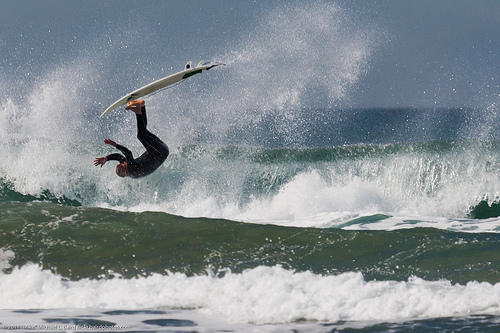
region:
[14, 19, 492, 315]
He is in the ocean.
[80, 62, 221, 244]
He is surfing.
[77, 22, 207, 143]
the board is white and black.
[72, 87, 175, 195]
He is wearing a wet suit.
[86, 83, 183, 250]
He is wet.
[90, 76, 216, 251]
He is upside down.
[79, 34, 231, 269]
he is falling.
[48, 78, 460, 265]
The wave is large.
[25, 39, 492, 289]
The wave is splashing.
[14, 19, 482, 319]
The water is dirty.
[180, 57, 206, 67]
The fins on the bottom of the surfboard.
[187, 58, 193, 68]
The fin on the bottom of the surfboard with a black circle.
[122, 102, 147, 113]
The feet of the surfer.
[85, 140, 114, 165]
The hands of the surfer.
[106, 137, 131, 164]
The arms of the surfer.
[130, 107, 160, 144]
The legs of the surfer.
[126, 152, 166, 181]
The chest and back area of the surfer.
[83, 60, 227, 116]
The surfboard the surfer is riding.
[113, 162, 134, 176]
The head of the surfer.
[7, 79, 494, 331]
The waves of the ocean.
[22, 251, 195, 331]
froth from the breaking wave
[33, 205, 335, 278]
wave in the ocean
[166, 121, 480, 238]
wave breaking in the ocean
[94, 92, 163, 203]
man falling in the air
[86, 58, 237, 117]
surfboard in the air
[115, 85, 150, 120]
man's feet leaving surfboard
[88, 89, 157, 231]
upside down man in ocean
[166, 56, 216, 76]
fins on the bottom of surfboard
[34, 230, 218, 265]
water in the ocean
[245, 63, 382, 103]
water droplets in the air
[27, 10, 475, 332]
man surfing on waves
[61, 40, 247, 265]
man on a surfboard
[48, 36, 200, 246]
man upside down in air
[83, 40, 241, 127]
white short surfboard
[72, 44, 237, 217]
man wearing a wet suit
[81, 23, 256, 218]
man falling down in air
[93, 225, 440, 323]
crashing waves in ocean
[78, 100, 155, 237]
man bent over upside down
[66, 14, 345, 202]
white water spraying in the air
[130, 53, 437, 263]
ocean and horizon line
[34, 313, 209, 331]
foam on the water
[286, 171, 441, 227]
wave crashing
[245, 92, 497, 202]
spray from the wave crashing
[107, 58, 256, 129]
surfboard is white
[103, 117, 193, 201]
surfboarder is upside down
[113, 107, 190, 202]
wetsuit is black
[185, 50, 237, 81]
two fins on the bottom of surfboard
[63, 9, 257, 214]
spray from the wave and surfer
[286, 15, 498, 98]
sky is blue and clear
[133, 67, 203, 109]
cord to the surfboard to attach to surfer